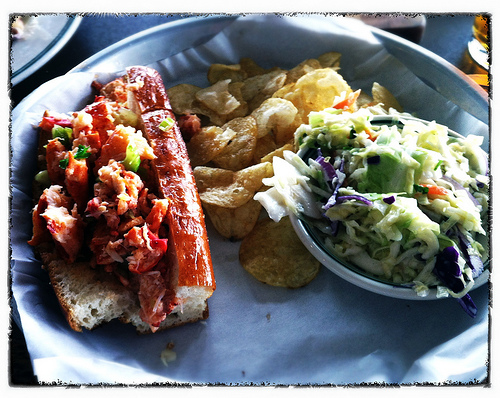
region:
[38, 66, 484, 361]
food on the plate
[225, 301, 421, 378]
napkin on the plate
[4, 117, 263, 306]
red bread that looks tasty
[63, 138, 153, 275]
meat inside bread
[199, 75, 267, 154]
crispy potato chips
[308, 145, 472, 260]
salad in a bowl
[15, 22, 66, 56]
a white plate with blue border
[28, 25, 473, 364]
a very good tasty meal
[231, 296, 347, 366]
a crumb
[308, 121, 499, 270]
a salad with lettuce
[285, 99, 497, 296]
a bowl of coleslaw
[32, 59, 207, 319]
a bun filled with meat and vegetables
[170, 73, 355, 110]
some potato chips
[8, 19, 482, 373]
a plate full of colorful food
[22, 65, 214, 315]
a big sandwich filled with things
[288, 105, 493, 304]
a side salad with cabbage and lettuce and carrot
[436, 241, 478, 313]
a piece of cabbage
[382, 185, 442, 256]
a piece of lettuce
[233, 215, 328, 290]
a single potato chip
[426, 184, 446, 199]
a piece of shredded carrot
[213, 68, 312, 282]
potato chips on the top of the table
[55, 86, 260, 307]
toasted bread with meat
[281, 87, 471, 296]
a bowl of salad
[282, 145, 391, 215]
purple cabbage salad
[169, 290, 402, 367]
white paper plate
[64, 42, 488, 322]
food in the plate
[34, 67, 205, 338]
sandwich on the plate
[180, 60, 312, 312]
potato chip in the table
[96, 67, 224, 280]
toasted bread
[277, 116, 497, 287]
bowl of salad on the side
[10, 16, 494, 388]
a tasty looking meal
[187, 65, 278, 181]
crisp potato chips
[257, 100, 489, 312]
a healthy side salad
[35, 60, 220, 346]
a sandwich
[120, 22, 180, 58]
a dish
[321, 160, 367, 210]
a small piece of red cabbage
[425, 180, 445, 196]
a small piece of carot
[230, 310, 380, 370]
a paper liner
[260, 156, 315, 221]
a piece of lettuce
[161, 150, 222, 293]
the crispy edge of a sandwich roll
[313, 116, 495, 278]
small bowl of coleslaw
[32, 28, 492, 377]
A dish with a sandwich, chips and coleslaw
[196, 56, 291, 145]
A pile of potato chips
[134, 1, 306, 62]
Napkin covering a dinner plate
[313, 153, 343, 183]
Strip of cabbage in the coleslaw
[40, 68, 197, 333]
A meaty submarine sandwich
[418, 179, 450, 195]
Strips of carrots inside coleslaw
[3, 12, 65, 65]
Another plate of food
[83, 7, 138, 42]
A blue diner table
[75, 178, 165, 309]
Chunks of meat on a sandwich, possibly beef.